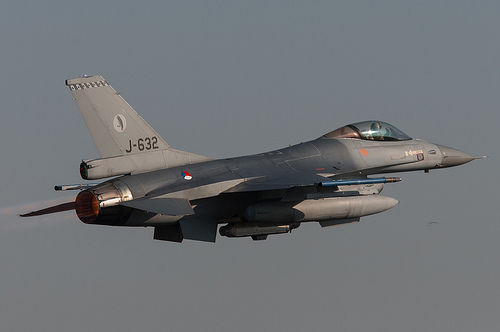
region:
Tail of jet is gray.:
[77, 77, 143, 155]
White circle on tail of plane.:
[108, 101, 129, 133]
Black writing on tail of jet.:
[120, 129, 174, 179]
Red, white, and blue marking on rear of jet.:
[173, 161, 210, 218]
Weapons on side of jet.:
[291, 165, 357, 246]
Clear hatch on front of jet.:
[339, 118, 416, 151]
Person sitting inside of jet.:
[353, 109, 410, 162]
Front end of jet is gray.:
[436, 139, 473, 207]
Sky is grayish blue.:
[172, 57, 256, 104]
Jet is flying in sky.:
[88, 78, 327, 243]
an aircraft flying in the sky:
[12, 62, 490, 269]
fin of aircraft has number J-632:
[58, 66, 187, 158]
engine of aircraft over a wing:
[71, 139, 201, 184]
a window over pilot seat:
[328, 105, 415, 147]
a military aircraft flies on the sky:
[16, 56, 498, 283]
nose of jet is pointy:
[425, 132, 495, 175]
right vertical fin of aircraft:
[111, 192, 198, 227]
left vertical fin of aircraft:
[11, 195, 76, 222]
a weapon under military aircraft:
[178, 192, 426, 230]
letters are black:
[121, 129, 168, 167]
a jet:
[25, 73, 494, 246]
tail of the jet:
[60, 72, 147, 143]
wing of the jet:
[277, 171, 394, 183]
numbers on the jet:
[120, 131, 168, 152]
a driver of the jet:
[352, 111, 399, 145]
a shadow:
[215, 205, 307, 234]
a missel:
[262, 196, 401, 224]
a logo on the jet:
[174, 169, 204, 187]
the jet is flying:
[25, 81, 476, 289]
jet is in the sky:
[45, 68, 487, 243]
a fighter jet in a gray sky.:
[14, 60, 484, 291]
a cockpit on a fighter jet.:
[310, 90, 438, 154]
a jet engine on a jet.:
[70, 162, 132, 229]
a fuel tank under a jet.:
[221, 179, 398, 254]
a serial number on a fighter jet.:
[108, 111, 169, 163]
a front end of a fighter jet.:
[318, 105, 490, 201]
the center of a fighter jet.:
[138, 116, 303, 237]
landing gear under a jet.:
[233, 216, 282, 256]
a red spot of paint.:
[353, 142, 378, 170]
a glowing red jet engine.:
[38, 177, 132, 278]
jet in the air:
[24, 56, 444, 278]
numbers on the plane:
[105, 117, 177, 172]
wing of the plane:
[249, 173, 380, 252]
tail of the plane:
[49, 99, 171, 180]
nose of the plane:
[433, 117, 489, 192]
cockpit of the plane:
[348, 106, 406, 149]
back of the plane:
[60, 157, 146, 234]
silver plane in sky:
[13, 23, 488, 278]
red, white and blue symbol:
[169, 163, 201, 193]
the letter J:
[119, 133, 138, 158]